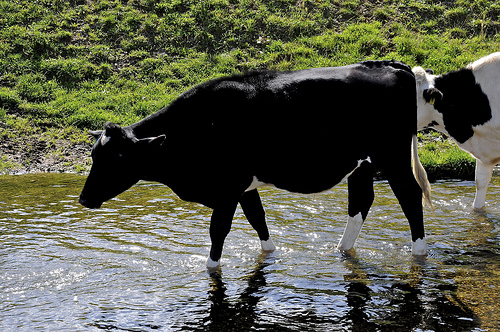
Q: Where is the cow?
A: Water.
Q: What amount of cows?
A: Two.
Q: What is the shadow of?
A: Cow.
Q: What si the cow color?
A: Black.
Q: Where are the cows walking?
A: Stream.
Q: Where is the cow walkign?
A: Stream.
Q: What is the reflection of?
A: Cow.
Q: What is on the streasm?
A: Grass.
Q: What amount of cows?
A: Two.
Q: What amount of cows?
A: Two.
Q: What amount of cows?
A: Two.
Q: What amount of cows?
A: Two.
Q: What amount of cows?
A: Two.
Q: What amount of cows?
A: Two.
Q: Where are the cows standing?
A: In the water.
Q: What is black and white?
A: The cows.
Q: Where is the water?
A: Under the cows.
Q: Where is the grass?
A: Behind the cows.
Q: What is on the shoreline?
A: Grass.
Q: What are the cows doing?
A: Walking in the water.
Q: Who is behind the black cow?
A: The white and black cow.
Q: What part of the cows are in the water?
A: Their feet.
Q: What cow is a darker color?
A: The cow in front.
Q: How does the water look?
A: Shallow.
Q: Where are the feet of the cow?
A: In the water.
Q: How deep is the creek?
A: Shallow.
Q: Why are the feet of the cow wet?
A: Are in water.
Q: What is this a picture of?
A: Cows.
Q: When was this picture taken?
A: Daytime.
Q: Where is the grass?
A: Next to the water.